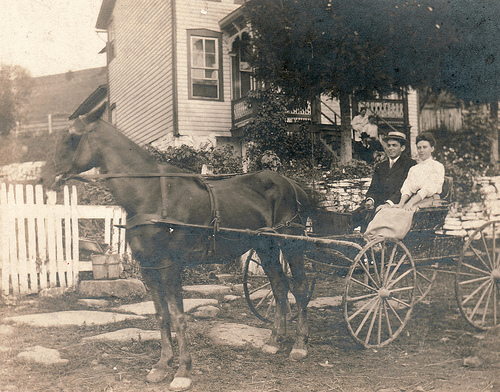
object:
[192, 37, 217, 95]
curtain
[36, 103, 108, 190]
head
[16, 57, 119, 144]
hill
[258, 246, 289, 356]
leg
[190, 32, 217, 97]
window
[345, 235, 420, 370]
wheel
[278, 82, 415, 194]
stairs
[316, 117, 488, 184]
mans head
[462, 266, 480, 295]
spokes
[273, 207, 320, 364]
leg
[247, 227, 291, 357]
leg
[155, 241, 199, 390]
leg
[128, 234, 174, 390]
leg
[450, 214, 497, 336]
wheel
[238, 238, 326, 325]
wheel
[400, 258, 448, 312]
wheel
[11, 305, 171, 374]
rocks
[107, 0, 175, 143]
side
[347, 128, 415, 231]
man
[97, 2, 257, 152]
house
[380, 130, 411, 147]
hat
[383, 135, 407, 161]
head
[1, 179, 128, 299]
fence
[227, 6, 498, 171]
tree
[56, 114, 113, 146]
blinders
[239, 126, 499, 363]
carriage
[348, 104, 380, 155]
people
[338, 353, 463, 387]
dirt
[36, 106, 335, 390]
horse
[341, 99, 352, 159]
trunk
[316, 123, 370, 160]
step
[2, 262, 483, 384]
dirt yard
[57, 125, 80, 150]
eyes